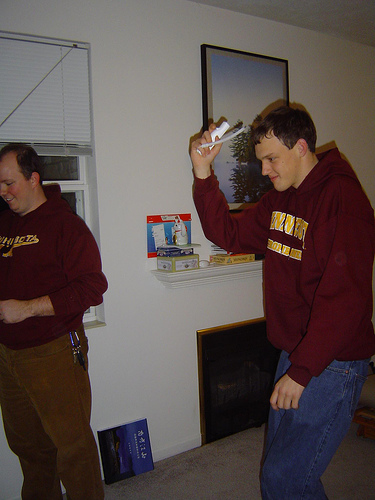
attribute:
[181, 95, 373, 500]
person — young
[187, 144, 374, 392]
sweater — burgundy, red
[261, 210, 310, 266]
logo — yellow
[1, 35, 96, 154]
blinds — white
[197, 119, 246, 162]
remote — wii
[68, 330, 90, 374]
keys — on hip, ringed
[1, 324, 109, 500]
pants — brown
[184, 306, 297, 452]
fireplace — built in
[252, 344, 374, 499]
jeans — blue